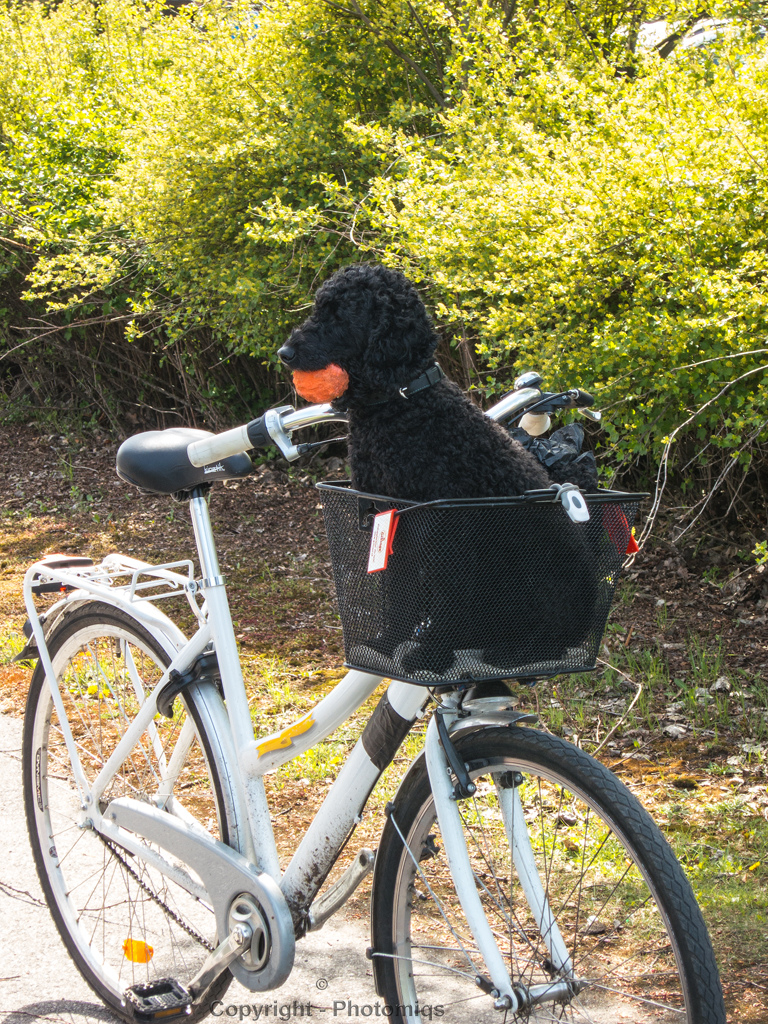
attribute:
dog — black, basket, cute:
[264, 272, 545, 511]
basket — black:
[318, 466, 650, 685]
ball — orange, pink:
[301, 334, 380, 418]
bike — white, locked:
[48, 443, 484, 963]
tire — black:
[354, 722, 753, 1009]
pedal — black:
[129, 964, 211, 1020]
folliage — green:
[495, 61, 731, 348]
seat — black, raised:
[101, 381, 250, 516]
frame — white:
[166, 514, 307, 829]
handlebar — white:
[239, 373, 411, 477]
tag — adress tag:
[332, 497, 430, 590]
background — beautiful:
[56, 10, 728, 311]